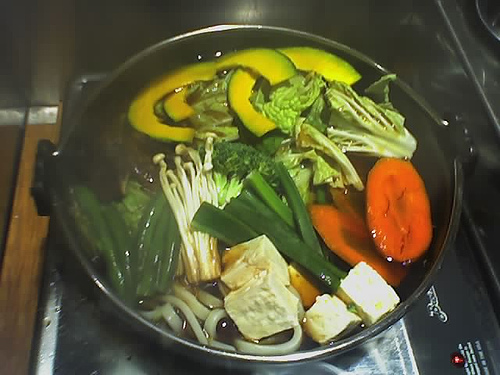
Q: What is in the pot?
A: Vegetables.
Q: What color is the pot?
A: Black.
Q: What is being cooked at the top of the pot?
A: Avocado slices.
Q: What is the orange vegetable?
A: Carrots.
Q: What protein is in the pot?
A: Tofu.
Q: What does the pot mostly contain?
A: Vegetables.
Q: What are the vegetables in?
A: A pot.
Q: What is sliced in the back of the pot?
A: Avocado.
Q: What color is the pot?
A: Silver.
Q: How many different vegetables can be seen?
A: Seven.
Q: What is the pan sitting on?
A: Stove.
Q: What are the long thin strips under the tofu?
A: Noodles.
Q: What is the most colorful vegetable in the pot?
A: Carrots.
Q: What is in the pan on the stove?
A: Liquid.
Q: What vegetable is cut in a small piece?
A: A carrot.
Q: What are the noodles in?
A: Brown broth.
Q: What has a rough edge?
A: Green scallions.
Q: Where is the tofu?
A: In the soup.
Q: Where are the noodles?
A: In the soup.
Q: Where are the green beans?
A: In the soup.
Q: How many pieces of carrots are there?
A: Three.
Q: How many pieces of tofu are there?
A: Four.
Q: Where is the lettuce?
A: In the soup.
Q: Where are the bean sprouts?
A: In the soup.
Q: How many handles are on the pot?
A: Two.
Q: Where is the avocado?
A: In the pot.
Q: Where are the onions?
A: In the pot.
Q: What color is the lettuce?
A: Green.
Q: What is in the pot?
A: Vegetables.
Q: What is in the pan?
A: There are a variety of vegetables in the pan.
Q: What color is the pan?
A: The pan is black.